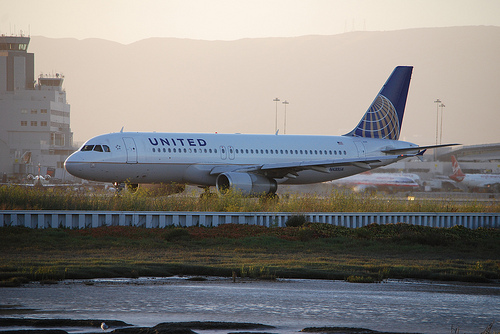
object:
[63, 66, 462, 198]
airplane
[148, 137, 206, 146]
united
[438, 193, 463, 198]
tarmac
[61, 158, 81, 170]
nose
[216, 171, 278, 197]
engine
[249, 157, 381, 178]
wing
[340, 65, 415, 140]
tail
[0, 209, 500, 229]
fence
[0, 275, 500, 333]
pond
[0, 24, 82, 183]
control tower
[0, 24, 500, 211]
airport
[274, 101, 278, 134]
poles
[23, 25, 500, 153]
mountains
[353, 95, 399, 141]
globe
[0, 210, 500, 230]
wall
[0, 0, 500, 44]
sky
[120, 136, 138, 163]
door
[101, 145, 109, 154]
windows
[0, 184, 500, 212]
grass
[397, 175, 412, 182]
flag